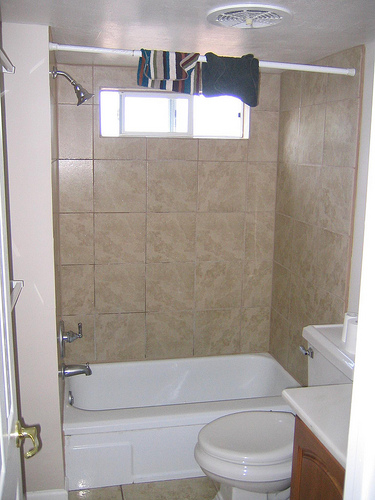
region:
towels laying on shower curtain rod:
[116, 29, 281, 112]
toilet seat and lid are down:
[179, 397, 317, 487]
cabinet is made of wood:
[285, 416, 347, 497]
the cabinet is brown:
[282, 417, 352, 499]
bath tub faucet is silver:
[58, 317, 109, 387]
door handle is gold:
[4, 409, 60, 460]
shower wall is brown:
[58, 49, 374, 332]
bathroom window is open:
[105, 84, 255, 144]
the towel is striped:
[137, 42, 211, 106]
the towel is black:
[196, 43, 265, 107]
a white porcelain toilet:
[184, 312, 356, 497]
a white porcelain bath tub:
[54, 345, 302, 487]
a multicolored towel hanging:
[132, 44, 200, 97]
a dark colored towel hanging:
[199, 49, 259, 105]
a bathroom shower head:
[47, 61, 95, 111]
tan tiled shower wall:
[66, 138, 345, 374]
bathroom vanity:
[279, 376, 345, 498]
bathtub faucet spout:
[57, 359, 95, 378]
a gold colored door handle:
[11, 414, 42, 461]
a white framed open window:
[99, 84, 249, 142]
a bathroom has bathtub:
[5, 3, 362, 499]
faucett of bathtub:
[64, 353, 97, 384]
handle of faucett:
[57, 312, 89, 349]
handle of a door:
[9, 410, 56, 467]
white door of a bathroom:
[0, 51, 28, 495]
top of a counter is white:
[283, 379, 366, 482]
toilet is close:
[188, 406, 296, 498]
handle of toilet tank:
[290, 337, 320, 364]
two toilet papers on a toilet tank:
[333, 306, 359, 367]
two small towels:
[126, 36, 269, 117]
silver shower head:
[48, 68, 95, 106]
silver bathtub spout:
[56, 360, 93, 382]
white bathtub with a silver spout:
[60, 350, 311, 490]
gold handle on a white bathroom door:
[5, 416, 42, 463]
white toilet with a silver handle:
[193, 323, 358, 498]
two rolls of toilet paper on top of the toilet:
[301, 309, 366, 375]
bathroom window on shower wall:
[100, 86, 251, 139]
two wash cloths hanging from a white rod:
[136, 47, 261, 107]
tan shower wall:
[54, 64, 277, 365]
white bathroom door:
[1, 124, 44, 499]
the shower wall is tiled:
[39, 46, 345, 387]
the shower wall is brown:
[50, 59, 368, 367]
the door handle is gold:
[11, 405, 51, 461]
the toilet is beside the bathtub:
[50, 311, 359, 495]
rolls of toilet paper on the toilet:
[290, 297, 371, 386]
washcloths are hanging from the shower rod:
[35, 25, 360, 132]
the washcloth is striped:
[128, 46, 204, 102]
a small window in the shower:
[93, 76, 268, 159]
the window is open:
[91, 78, 260, 162]